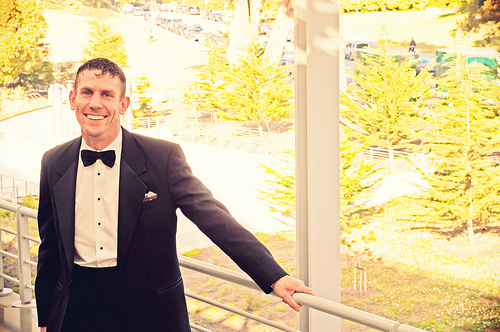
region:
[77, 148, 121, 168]
Black bow tie on a collar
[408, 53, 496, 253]
An evergreen tree outside the window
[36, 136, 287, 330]
A black men's suit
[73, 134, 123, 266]
A white button up shirt and bow tie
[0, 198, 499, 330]
A grey metal handrail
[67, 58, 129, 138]
A smiling man's face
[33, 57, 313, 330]
A smiling man in a suit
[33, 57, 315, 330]
A man leaning on a handrail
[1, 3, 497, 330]
Grassy background with evergreen trees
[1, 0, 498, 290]
Scattered ever green trees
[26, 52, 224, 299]
the man is wearing a suit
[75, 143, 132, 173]
the tie is black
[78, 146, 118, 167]
the tie is black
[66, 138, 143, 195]
the tie is black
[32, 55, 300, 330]
Man wearing a tuxedo.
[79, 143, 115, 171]
Black bow tie on man.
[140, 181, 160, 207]
White handkerchief in the pocket.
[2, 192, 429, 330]
Gray railing behind the man.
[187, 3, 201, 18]
Vehicle in the background.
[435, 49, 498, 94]
Green structure in the background.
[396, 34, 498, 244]
Tree in the background.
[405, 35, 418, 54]
Person in the background.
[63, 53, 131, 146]
Short brown hair on the man.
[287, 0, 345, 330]
Gray pole on the building.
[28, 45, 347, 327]
a man wearing a tuxedo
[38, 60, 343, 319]
a man holding the rail of a balcony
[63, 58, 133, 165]
a man wearing a bow tie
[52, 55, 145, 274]
a man wearing a white shirt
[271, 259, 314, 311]
the hand of a man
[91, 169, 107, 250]
the buttons on a shirt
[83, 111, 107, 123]
the smile of a man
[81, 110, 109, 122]
the mouth of a man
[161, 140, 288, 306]
the arm of a man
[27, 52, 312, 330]
man dressed in tuxedo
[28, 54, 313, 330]
smiling man dressed in tuxedo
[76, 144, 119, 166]
bow tie of man dressed in tuxedo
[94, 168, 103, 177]
black button on white shirt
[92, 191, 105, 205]
black button on white shirt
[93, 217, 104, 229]
black button on white shirt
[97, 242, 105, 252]
black button on white shirt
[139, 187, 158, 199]
hankerchief in pocket of suit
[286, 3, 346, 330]
white post of building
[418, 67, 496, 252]
tree